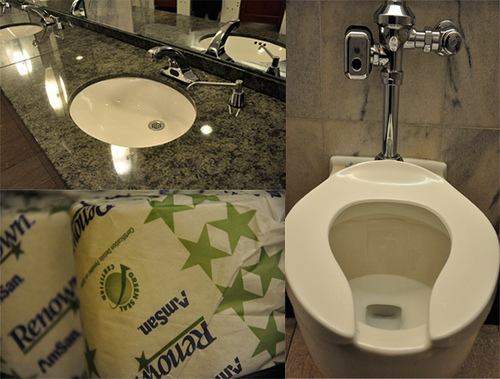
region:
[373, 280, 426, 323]
bowl of the toilet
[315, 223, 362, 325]
seat of the toilet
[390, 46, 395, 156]
pole on the toilet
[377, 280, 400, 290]
water in the toilet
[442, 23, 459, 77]
lever of the toilet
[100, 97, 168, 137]
drain of the sink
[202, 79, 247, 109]
faucest of the sink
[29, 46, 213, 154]
sink on the counter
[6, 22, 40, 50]
sink on the counter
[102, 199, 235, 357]
toilet paper is wrapped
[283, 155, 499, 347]
a white plastic toilet seat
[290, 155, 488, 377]
a white porcelain toilet bowl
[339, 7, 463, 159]
toilet chrome flush valve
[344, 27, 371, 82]
automatic chrome flusher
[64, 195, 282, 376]
a paper wrapped roll of toilet paper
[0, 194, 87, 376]
a paper wrapped roll of toilet paper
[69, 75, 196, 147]
a white inset bathroom sink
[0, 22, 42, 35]
reflection of a white inset bathroom sink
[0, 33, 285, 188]
a grey marble countertop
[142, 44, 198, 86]
a chrome bathroom faucet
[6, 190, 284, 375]
paper wrapping with stars around toilet rolls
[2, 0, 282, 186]
sinks set into stone counters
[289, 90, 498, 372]
white seat over white toilet bowl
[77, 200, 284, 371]
wrinkles in packaging for bathroom tissue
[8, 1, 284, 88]
mirror behind long counter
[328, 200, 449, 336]
water at bottom of toilet bowl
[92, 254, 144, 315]
words around circle with green checkmark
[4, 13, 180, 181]
white lighting fixtures reflected on counter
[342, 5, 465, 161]
silver plumbing attaching water to toilet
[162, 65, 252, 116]
curved arm of pump behind sink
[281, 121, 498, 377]
white toilet in bathroom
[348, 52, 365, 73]
black button on toilet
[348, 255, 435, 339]
water in toilet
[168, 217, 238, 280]
stars on paper cover on toilet tissue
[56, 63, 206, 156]
white sink in countertop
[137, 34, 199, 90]
faucet over sink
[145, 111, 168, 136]
metal drain in sink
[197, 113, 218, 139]
white light reflecting on counter top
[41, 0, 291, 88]
mirror in front of sink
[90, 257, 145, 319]
logo on toilet tissue cover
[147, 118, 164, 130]
a chrome bathroom sink drain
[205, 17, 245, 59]
reflection of a bathroom faucet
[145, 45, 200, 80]
an automatic bathroom faucet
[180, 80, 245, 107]
a chrome soap pump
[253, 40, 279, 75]
reflection of a chrome soap pump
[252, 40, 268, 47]
three sink overflow drainage holes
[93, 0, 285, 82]
a wall mounted bathroom vanity mirror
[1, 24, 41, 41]
reflection of an bathroom sink basin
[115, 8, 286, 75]
reflection of a marble countertop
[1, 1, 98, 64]
reflection of a marble countertop